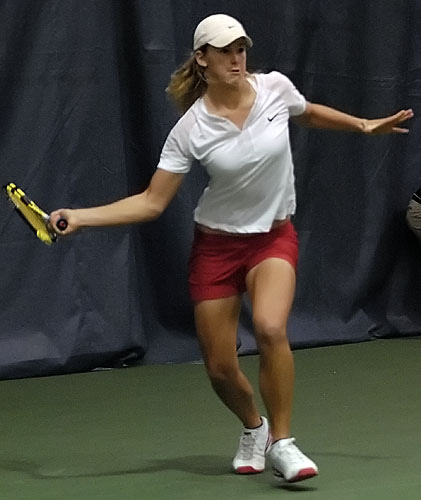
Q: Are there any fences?
A: No, there are no fences.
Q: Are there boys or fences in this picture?
A: No, there are no fences or boys.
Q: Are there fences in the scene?
A: No, there are no fences.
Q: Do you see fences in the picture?
A: No, there are no fences.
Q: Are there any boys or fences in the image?
A: No, there are no fences or boys.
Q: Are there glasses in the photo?
A: No, there are no glasses.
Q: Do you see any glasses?
A: No, there are no glasses.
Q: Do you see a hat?
A: Yes, there is a hat.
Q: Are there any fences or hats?
A: Yes, there is a hat.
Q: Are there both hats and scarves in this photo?
A: No, there is a hat but no scarves.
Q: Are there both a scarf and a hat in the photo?
A: No, there is a hat but no scarves.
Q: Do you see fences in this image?
A: No, there are no fences.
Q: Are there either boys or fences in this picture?
A: No, there are no fences or boys.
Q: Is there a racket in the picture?
A: Yes, there is a racket.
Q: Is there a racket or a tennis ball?
A: Yes, there is a racket.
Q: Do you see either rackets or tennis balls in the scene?
A: Yes, there is a racket.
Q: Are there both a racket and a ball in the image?
A: No, there is a racket but no balls.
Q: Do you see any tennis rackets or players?
A: Yes, there is a tennis racket.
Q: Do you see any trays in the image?
A: No, there are no trays.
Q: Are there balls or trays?
A: No, there are no trays or balls.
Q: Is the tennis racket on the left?
A: Yes, the tennis racket is on the left of the image.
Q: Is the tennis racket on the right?
A: No, the tennis racket is on the left of the image.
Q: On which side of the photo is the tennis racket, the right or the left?
A: The racket is on the left of the image.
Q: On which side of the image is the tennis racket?
A: The racket is on the left of the image.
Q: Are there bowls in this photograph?
A: No, there are no bowls.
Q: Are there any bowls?
A: No, there are no bowls.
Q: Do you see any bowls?
A: No, there are no bowls.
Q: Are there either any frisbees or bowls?
A: No, there are no bowls or frisbees.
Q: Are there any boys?
A: No, there are no boys.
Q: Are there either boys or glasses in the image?
A: No, there are no boys or glasses.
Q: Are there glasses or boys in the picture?
A: No, there are no boys or glasses.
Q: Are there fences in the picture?
A: No, there are no fences.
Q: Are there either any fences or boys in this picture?
A: No, there are no fences or boys.